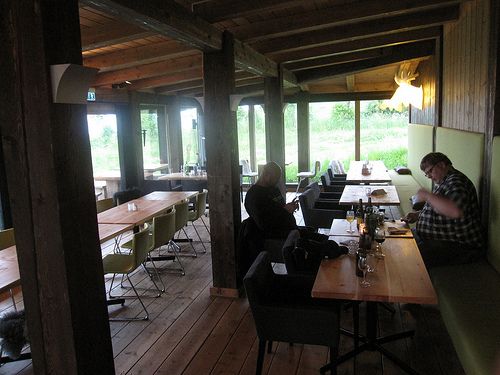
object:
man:
[410, 151, 485, 267]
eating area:
[0, 2, 500, 372]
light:
[387, 73, 425, 111]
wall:
[438, 1, 499, 129]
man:
[244, 160, 300, 238]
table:
[97, 188, 200, 223]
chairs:
[153, 209, 184, 276]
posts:
[202, 26, 242, 296]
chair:
[241, 252, 342, 375]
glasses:
[357, 250, 379, 288]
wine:
[357, 197, 365, 224]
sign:
[84, 88, 97, 102]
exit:
[86, 113, 116, 197]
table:
[345, 159, 390, 182]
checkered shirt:
[415, 169, 486, 247]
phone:
[288, 196, 295, 203]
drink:
[411, 195, 425, 210]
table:
[309, 235, 440, 306]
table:
[327, 217, 414, 238]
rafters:
[78, 1, 461, 59]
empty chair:
[102, 225, 160, 321]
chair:
[299, 188, 345, 226]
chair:
[297, 160, 322, 194]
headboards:
[403, 123, 483, 233]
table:
[339, 182, 401, 208]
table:
[1, 223, 136, 292]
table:
[159, 171, 216, 184]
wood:
[160, 171, 207, 180]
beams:
[81, 1, 296, 87]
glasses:
[424, 167, 437, 176]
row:
[106, 187, 208, 296]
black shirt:
[244, 185, 297, 237]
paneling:
[410, 57, 438, 125]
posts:
[264, 77, 287, 203]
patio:
[0, 163, 449, 375]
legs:
[318, 339, 368, 375]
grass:
[370, 123, 403, 166]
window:
[357, 101, 410, 176]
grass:
[312, 131, 351, 173]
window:
[308, 100, 356, 180]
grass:
[284, 159, 299, 184]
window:
[253, 102, 298, 183]